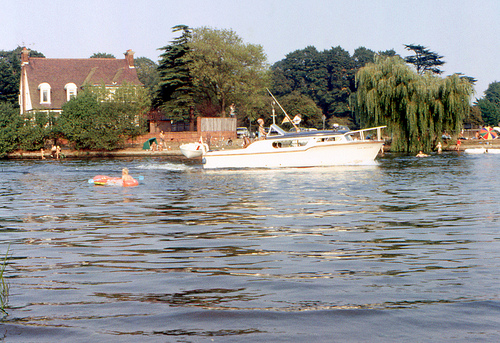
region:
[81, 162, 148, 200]
raft in the water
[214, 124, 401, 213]
boat moving in the water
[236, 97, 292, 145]
woman driving the boat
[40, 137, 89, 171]
people sitting on the wall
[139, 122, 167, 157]
shade tent is green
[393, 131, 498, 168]
people in the water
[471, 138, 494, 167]
beach on the water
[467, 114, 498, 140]
umbrella at the beach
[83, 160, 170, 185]
raft has blue oars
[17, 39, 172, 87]
house has two chimneys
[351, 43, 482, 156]
A big beautiful weeping willow tree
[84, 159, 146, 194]
A person floating on a tube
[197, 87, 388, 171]
A boat floating on the water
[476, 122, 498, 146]
a multi colored umbrella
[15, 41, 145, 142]
A big house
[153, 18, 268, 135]
A big bushy tree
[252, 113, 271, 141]
A woman driving a boat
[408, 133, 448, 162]
People swimming in the lake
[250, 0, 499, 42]
A piece of clear sky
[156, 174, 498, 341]
Ripples in a lake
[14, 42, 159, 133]
large two story house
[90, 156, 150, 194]
person on float in water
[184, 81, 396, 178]
white boat on water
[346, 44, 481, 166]
tree with long strands of green leaves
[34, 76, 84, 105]
two white windows on house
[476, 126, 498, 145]
multi colored umbrella on shore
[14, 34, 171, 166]
house sitting in front of water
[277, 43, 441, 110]
trees with dark green leaves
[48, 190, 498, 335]
ripples in calm water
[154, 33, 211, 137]
large coniferous tree beside house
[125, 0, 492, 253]
a boat in the water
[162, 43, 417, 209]
a big boat in the water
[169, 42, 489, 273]
a white boat in the water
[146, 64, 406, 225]
a boat moving in the water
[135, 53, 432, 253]
a white boat moving in the water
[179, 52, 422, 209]
a large boat in the water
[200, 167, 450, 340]
a body of water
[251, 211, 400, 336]
a body of calm water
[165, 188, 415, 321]
a body of water that is calm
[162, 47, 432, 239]
a body of water with a boat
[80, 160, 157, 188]
A man on a float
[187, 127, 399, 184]
A boat in the water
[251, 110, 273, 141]
A person driving a boat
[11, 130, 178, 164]
People on the beach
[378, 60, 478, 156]
A willow tree along the water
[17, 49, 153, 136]
A house along the water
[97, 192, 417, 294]
Waves in the water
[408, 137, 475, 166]
People floating in the water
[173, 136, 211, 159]
A small boat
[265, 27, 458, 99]
Big trees in the back ground